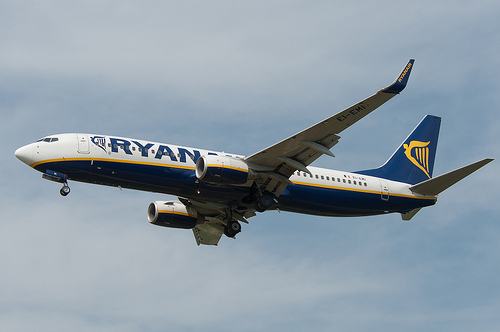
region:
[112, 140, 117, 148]
a window on a plane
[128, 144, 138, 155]
a window on a plane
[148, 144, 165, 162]
a window on a plane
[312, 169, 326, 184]
a window on a plane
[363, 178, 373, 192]
a window on a plane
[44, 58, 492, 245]
white blue and yellow plane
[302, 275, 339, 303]
white clouds in blue sky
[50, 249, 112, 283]
white clouds in blue sky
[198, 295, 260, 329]
white clouds in blue sky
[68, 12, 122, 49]
white clouds in blue sky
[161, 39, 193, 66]
white clouds in blue sky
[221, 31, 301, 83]
white clouds in blue sky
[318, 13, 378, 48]
white clouds in blue sky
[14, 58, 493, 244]
a large passenger jet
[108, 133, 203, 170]
blue word on the plane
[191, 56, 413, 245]
wings of the jet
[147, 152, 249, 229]
twin engines of the jet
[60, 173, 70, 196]
landing gear of the jet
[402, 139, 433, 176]
logo on the tail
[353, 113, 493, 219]
tail of the plane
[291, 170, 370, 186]
passenger windows on the side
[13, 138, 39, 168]
nose of the plane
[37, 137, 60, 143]
front windows of the plane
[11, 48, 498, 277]
a plane color white and blue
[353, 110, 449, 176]
the vertical stabilizer is blue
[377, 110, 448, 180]
a symbol on vertical stabilizer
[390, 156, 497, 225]
horizontal stabilizer of plane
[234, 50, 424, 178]
a wing on the right side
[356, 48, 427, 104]
tip of the wing is raised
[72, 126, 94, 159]
front door of plane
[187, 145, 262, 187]
an engine in front a plane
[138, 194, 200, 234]
an engine in front a plane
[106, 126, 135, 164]
the letter R on the plane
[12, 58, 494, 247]
a large airplane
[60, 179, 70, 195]
landing gear of the airplane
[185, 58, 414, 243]
wings of the airplane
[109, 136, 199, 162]
blue letters on the plane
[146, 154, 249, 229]
engines on the plane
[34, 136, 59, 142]
front windows of the plane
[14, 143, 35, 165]
nose of the airplane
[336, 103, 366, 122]
letters on the bottom of the wing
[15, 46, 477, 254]
blue white and yellow plane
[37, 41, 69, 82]
white clouds in blue sky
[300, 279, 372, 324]
white clouds in blue sky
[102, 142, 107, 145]
A window on a plane.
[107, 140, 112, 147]
A window on a plane.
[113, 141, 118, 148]
A window on a plane.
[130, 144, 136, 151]
A window on a plane.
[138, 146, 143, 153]
A window on a plane.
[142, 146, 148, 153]
A window on a plane.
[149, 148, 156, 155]
A window on a plane.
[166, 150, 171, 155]
A window on a plane.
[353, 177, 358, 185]
A window on a plane.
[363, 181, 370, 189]
A window on a plane.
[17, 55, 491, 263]
Blue and white plane in the sky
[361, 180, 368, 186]
small glass window on the airplane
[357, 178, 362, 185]
small glass window on the airplane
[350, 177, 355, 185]
small glass window on the airplane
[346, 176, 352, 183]
small glass window on the airplane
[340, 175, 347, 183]
small glass window on the airplane